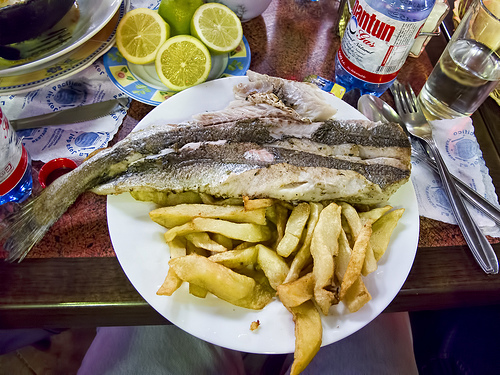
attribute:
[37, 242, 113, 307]
table — wooden, brown, white, wood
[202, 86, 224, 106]
plate — white, round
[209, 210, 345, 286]
french fries — crispy, sitting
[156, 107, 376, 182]
fish — fried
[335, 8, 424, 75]
bottle — blue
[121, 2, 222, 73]
fruit — sliced, green, lemon, yellow, lime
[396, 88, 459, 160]
fork — silver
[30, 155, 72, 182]
cap — red